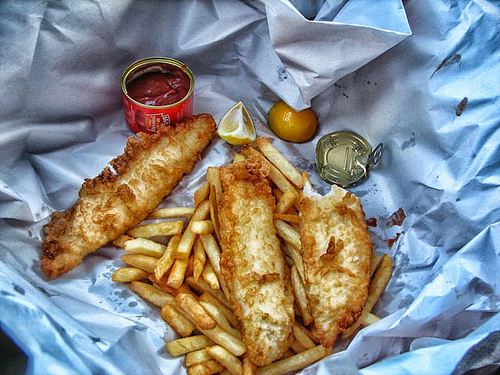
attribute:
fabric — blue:
[0, 0, 494, 373]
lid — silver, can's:
[314, 128, 385, 190]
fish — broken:
[297, 177, 378, 352]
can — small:
[108, 61, 249, 139]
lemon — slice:
[217, 100, 258, 145]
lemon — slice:
[208, 92, 259, 149]